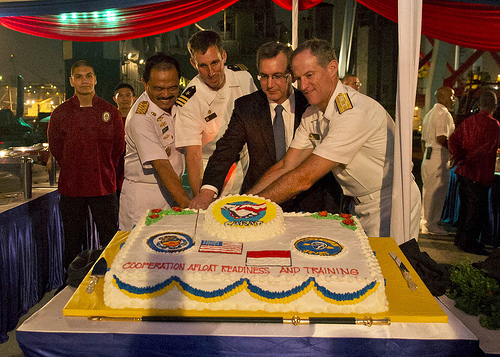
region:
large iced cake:
[95, 188, 397, 328]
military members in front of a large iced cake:
[96, 14, 407, 321]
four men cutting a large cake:
[97, 21, 392, 323]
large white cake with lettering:
[96, 191, 393, 336]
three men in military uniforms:
[111, 26, 401, 206]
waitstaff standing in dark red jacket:
[38, 45, 123, 237]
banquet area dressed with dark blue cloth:
[6, 139, 57, 304]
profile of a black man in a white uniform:
[421, 57, 458, 220]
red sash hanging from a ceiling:
[3, 3, 252, 48]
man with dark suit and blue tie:
[237, 22, 299, 205]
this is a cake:
[111, 194, 378, 321]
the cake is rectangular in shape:
[112, 227, 381, 306]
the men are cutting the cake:
[163, 173, 288, 206]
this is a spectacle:
[256, 72, 283, 79]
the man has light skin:
[276, 173, 294, 190]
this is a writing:
[124, 260, 360, 280]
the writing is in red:
[124, 258, 359, 280]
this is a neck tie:
[274, 118, 283, 143]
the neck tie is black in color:
[273, 123, 280, 130]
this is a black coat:
[242, 110, 263, 132]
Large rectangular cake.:
[93, 188, 403, 318]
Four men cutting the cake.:
[101, 18, 433, 245]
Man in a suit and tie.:
[226, 47, 354, 223]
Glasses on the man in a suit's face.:
[254, 67, 305, 88]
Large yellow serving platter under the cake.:
[50, 214, 455, 331]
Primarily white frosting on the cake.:
[114, 201, 401, 317]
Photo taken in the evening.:
[4, 3, 494, 164]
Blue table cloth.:
[3, 164, 113, 346]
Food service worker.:
[33, 77, 118, 249]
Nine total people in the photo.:
[32, 37, 492, 264]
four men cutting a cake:
[80, 103, 415, 303]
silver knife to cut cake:
[383, 232, 426, 307]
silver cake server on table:
[69, 247, 121, 297]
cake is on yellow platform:
[67, 269, 442, 325]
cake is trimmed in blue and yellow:
[142, 272, 260, 306]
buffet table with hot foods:
[9, 122, 59, 292]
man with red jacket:
[48, 53, 113, 210]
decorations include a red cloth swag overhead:
[12, 7, 485, 49]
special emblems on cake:
[141, 199, 346, 266]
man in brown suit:
[240, 42, 292, 154]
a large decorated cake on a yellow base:
[103, 203, 409, 320]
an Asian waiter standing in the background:
[49, 62, 124, 258]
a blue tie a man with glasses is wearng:
[269, 101, 294, 163]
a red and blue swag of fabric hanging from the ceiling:
[0, 5, 250, 39]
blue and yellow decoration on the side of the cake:
[109, 266, 384, 321]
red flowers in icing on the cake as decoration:
[310, 207, 362, 234]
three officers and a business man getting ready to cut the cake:
[133, 26, 387, 198]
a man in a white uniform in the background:
[419, 79, 459, 229]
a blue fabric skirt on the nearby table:
[1, 196, 72, 321]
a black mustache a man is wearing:
[158, 93, 172, 103]